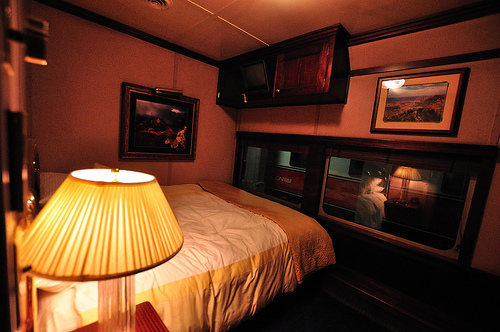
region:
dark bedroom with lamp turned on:
[56, 61, 463, 299]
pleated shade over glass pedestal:
[15, 160, 195, 290]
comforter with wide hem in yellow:
[55, 160, 335, 307]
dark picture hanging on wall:
[110, 65, 210, 170]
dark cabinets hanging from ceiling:
[205, 20, 360, 120]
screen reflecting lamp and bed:
[296, 115, 481, 260]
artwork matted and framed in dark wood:
[360, 65, 470, 135]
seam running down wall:
[150, 42, 205, 187]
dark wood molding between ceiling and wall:
[85, 10, 480, 62]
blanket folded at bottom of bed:
[180, 157, 346, 285]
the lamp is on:
[66, 168, 171, 308]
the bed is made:
[91, 160, 310, 315]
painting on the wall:
[111, 85, 224, 175]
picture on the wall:
[369, 65, 497, 150]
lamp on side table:
[36, 161, 164, 326]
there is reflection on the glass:
[221, 131, 495, 256]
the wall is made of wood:
[56, 80, 113, 170]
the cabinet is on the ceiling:
[213, 40, 355, 130]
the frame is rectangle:
[115, 75, 211, 167]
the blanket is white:
[173, 184, 250, 281]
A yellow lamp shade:
[22, 167, 183, 279]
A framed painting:
[366, 66, 471, 137]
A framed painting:
[118, 79, 197, 164]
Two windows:
[232, 141, 472, 256]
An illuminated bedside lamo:
[15, 162, 185, 323]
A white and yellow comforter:
[10, 176, 331, 328]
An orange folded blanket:
[197, 175, 333, 280]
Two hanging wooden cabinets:
[215, 22, 348, 107]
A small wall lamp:
[0, 15, 50, 73]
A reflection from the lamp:
[379, 77, 405, 89]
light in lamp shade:
[68, 149, 170, 194]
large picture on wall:
[115, 68, 220, 160]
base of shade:
[85, 264, 158, 329]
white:
[377, 114, 397, 129]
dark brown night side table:
[98, 299, 163, 330]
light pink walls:
[63, 46, 117, 113]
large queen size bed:
[22, 166, 359, 307]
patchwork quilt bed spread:
[198, 208, 319, 300]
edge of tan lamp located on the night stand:
[80, 269, 187, 287]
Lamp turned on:
[44, 162, 210, 288]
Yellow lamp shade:
[29, 167, 194, 284]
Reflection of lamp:
[369, 62, 419, 97]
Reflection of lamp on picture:
[358, 56, 430, 127]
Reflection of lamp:
[366, 150, 466, 264]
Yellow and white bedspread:
[211, 219, 326, 301]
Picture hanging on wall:
[109, 70, 224, 168]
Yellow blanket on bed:
[179, 165, 279, 234]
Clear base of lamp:
[93, 274, 153, 324]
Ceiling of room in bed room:
[171, 17, 266, 54]